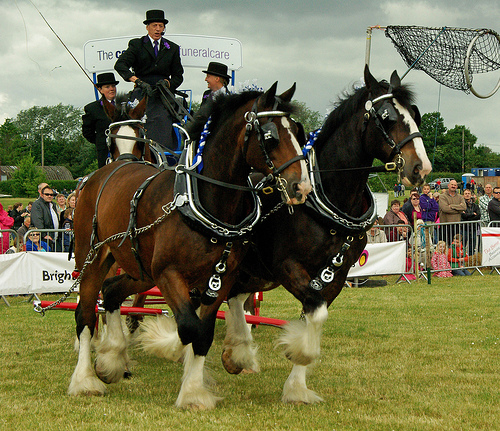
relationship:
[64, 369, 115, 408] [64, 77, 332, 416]
hooves on clydesdale horse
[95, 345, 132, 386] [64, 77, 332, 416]
hooves on clydesdale horse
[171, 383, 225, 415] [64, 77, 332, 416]
hooves on clydesdale horse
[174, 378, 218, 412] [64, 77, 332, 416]
hooves on clydesdale horse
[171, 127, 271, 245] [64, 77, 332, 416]
bridle on clydesdale horse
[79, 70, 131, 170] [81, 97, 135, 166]
person wearing suit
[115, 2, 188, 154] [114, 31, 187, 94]
man wearing suit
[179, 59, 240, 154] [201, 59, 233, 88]
person wearing hat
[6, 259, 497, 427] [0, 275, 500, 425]
grass on field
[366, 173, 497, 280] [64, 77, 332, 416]
crowd watching clydesdale horse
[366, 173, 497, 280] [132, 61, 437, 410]
crowd watching clydesdale horses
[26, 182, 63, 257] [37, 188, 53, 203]
man wearing sunglasses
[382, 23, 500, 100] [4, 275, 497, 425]
cone/shaped net above field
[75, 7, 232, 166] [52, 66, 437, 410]
men riding clydesdale horses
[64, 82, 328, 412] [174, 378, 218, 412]
clydesdale horse with hooves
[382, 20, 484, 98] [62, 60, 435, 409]
cone/shaped net by horses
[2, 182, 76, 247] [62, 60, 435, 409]
people watching horses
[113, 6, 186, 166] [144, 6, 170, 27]
man in a top hat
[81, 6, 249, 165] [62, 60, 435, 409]
three men riding horses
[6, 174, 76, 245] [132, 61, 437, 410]
people watching clydesdale horses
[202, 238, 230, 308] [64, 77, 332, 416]
bells on a clydesdale horse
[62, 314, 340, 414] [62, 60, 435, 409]
white hooves on horses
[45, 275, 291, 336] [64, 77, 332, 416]
red bars of a clydesdale horse